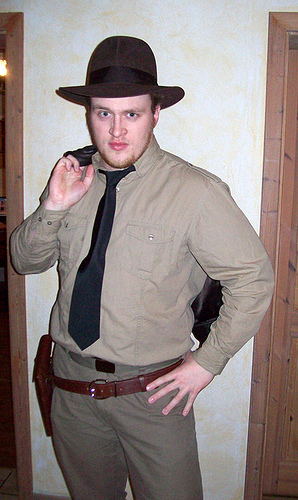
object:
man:
[9, 35, 275, 498]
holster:
[32, 333, 55, 438]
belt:
[51, 358, 184, 400]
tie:
[67, 165, 136, 351]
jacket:
[39, 145, 223, 347]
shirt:
[8, 132, 276, 374]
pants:
[49, 343, 204, 499]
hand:
[146, 349, 216, 417]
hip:
[133, 353, 195, 419]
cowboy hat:
[54, 35, 186, 109]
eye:
[126, 111, 138, 119]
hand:
[47, 153, 95, 204]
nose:
[109, 114, 128, 138]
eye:
[97, 110, 111, 118]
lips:
[109, 141, 130, 151]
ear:
[153, 103, 160, 126]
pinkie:
[182, 392, 198, 416]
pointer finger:
[146, 370, 174, 391]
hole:
[120, 388, 122, 391]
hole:
[110, 389, 113, 392]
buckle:
[89, 378, 111, 400]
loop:
[138, 375, 147, 393]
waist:
[48, 336, 189, 384]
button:
[148, 233, 154, 240]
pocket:
[119, 223, 176, 282]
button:
[47, 219, 52, 225]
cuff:
[39, 196, 70, 231]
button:
[38, 217, 42, 223]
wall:
[0, 1, 298, 500]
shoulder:
[50, 162, 103, 185]